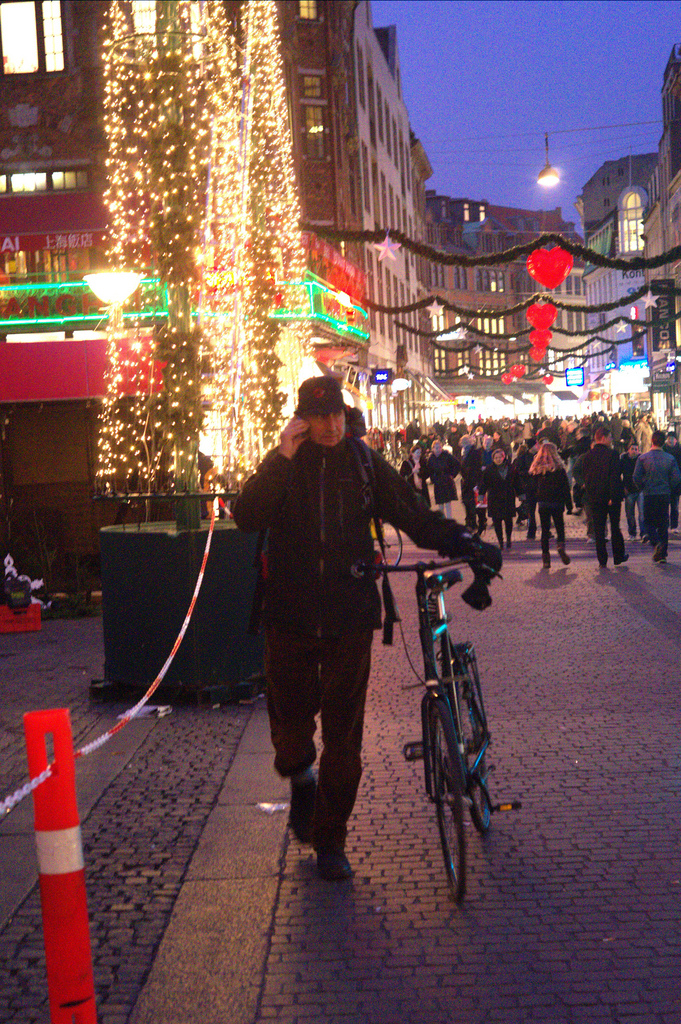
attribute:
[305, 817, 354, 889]
shoes — black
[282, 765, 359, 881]
shoes — black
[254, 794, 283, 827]
wrapper — plastic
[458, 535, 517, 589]
glove — black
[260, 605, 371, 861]
pants — brown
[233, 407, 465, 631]
jacket — brown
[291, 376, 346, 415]
hat — black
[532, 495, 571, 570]
jeans — blue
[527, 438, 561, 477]
hair — blonde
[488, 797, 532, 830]
reflector — orange